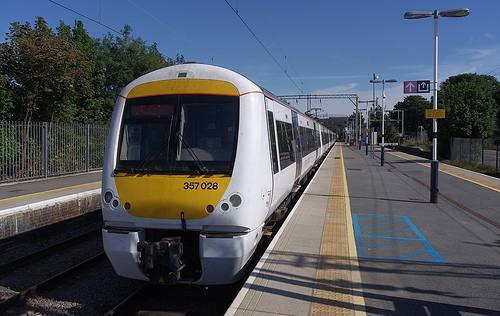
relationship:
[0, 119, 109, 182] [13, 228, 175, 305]
fence by tracks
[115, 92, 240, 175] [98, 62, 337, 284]
windows to bus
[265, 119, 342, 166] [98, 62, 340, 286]
windows in bus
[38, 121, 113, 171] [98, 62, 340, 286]
fence beside bus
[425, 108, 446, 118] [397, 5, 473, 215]
sign on light post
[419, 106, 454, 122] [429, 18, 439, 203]
sign on light post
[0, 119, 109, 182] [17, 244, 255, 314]
fence on tracks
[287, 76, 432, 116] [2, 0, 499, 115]
cloud in sky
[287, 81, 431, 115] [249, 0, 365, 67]
cloud in sky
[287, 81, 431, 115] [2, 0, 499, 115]
cloud in sky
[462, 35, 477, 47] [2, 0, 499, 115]
cloud in sky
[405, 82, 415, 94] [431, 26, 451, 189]
arrow on pole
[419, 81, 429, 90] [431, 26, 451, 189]
arrow on pole